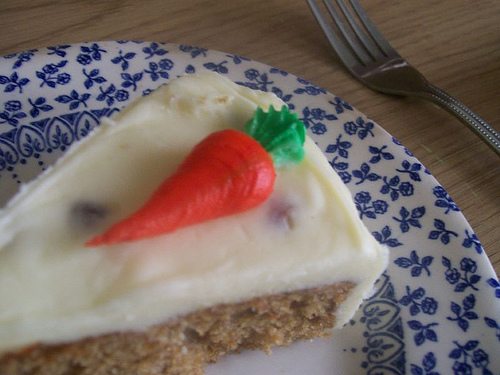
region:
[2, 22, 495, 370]
a piece of cake on a dish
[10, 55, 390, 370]
a piece of cake of carrot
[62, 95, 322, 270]
a carrot of frosting on top piece of cake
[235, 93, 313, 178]
green part of a carrot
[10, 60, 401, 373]
piece of cake is covered with white frosting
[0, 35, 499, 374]
a blue and white dish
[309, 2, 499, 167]
a fork on side of dish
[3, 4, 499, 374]
a dish on top a wood table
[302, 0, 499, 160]
a fork color silver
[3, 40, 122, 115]
flower decorations on border of plate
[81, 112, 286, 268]
frosting carrot on cake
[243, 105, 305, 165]
green frosting on cake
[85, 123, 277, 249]
orange frosting on cake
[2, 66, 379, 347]
frosting on cake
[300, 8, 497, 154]
metal spoon on table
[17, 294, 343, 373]
fluffy cake on plate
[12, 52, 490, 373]
plate on table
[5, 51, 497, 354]
plate has a pattern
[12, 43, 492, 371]
pate is blue and white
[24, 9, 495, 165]
table is made of wood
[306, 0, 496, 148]
A silver fork on a table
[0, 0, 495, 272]
A wooden table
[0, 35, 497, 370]
A blue and white plate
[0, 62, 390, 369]
A piece of cake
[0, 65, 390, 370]
A carrot cake on a plate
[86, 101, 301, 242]
A carrot made of icing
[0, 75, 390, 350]
White icing on the cake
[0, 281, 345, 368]
some brown sponge cake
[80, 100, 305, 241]
some orange and green icing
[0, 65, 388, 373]
A slice of carrot cake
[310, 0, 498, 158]
the fork is silver metal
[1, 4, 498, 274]
the table top is light wood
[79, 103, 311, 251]
the carrot is made of icing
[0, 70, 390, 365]
the slice of cake is on a plate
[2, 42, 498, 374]
the plate is blue and white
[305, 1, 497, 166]
the fork is next to the plate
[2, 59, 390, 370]
the slice of cake is triangular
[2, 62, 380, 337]
the cake icing is cream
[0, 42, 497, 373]
the plate has a blue and white floral pattern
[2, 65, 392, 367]
this is a slice of carrot cake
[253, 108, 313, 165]
green stem of the carrot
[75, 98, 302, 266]
orange and green carrot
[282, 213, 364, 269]
white cream cheese frosting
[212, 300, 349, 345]
brown carrot cake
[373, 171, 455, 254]
blue flowers on the plate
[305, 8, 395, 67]
four silver prongs on the fork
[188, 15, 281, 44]
part of a brown table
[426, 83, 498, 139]
handle of the fork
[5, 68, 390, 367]
cream cheese carrot cake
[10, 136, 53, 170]
designs on the plate